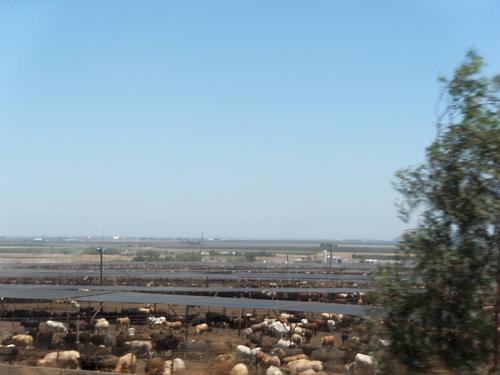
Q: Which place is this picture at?
A: It is at the pasture.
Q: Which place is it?
A: It is a pasture.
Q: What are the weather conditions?
A: It is clear.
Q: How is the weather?
A: It is clear.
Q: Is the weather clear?
A: Yes, it is clear.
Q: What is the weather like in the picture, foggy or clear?
A: It is clear.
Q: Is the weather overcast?
A: No, it is clear.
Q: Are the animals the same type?
A: Yes, all the animals are cows.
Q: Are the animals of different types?
A: No, all the animals are cows.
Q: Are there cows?
A: Yes, there is a cow.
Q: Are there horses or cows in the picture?
A: Yes, there is a cow.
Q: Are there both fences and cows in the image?
A: Yes, there are both a cow and a fence.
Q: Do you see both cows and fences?
A: Yes, there are both a cow and a fence.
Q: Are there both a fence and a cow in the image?
A: Yes, there are both a cow and a fence.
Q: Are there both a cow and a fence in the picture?
A: Yes, there are both a cow and a fence.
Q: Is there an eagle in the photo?
A: No, there are no eagles.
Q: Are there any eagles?
A: No, there are no eagles.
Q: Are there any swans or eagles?
A: No, there are no eagles or swans.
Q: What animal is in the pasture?
A: The animal is a cow.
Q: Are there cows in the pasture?
A: Yes, there is a cow in the pasture.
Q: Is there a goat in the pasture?
A: No, there is a cow in the pasture.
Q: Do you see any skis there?
A: No, there are no skis.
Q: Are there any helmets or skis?
A: No, there are no skis or helmets.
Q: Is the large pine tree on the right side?
A: Yes, the pine is on the right of the image.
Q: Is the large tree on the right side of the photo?
A: Yes, the pine is on the right of the image.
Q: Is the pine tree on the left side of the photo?
A: No, the pine tree is on the right of the image.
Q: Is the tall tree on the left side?
A: No, the pine tree is on the right of the image.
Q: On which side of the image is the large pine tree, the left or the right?
A: The pine is on the right of the image.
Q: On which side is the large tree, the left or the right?
A: The pine is on the right of the image.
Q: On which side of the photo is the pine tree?
A: The pine tree is on the right of the image.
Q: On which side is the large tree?
A: The pine tree is on the right of the image.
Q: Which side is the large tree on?
A: The pine tree is on the right of the image.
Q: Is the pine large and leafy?
A: Yes, the pine is large and leafy.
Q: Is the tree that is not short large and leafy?
A: Yes, the pine is large and leafy.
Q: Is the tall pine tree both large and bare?
A: No, the pine is large but leafy.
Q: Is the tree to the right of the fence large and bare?
A: No, the pine is large but leafy.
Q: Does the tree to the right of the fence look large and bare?
A: No, the pine is large but leafy.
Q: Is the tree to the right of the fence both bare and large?
A: No, the pine is large but leafy.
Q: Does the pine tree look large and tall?
A: Yes, the pine tree is large and tall.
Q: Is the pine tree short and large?
A: No, the pine tree is large but tall.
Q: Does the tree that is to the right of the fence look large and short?
A: No, the pine tree is large but tall.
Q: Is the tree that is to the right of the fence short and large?
A: No, the pine tree is large but tall.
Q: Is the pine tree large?
A: Yes, the pine tree is large.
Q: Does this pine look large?
A: Yes, the pine is large.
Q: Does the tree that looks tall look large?
A: Yes, the pine is large.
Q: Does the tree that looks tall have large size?
A: Yes, the pine is large.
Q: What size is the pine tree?
A: The pine tree is large.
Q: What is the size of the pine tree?
A: The pine tree is large.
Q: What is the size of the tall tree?
A: The pine tree is large.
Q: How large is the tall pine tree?
A: The pine is large.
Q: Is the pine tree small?
A: No, the pine tree is large.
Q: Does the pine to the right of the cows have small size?
A: No, the pine is large.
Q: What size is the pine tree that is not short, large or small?
A: The pine tree is large.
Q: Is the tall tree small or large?
A: The pine tree is large.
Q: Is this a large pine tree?
A: Yes, this is a large pine tree.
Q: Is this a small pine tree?
A: No, this is a large pine tree.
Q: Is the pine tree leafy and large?
A: Yes, the pine tree is leafy and large.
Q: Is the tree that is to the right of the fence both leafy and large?
A: Yes, the pine tree is leafy and large.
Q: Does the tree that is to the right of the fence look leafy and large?
A: Yes, the pine tree is leafy and large.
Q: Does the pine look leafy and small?
A: No, the pine is leafy but large.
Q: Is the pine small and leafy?
A: No, the pine is leafy but large.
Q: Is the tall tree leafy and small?
A: No, the pine is leafy but large.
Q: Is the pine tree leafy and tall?
A: Yes, the pine tree is leafy and tall.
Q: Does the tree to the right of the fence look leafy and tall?
A: Yes, the pine tree is leafy and tall.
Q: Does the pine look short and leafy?
A: No, the pine is leafy but tall.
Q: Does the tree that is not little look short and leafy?
A: No, the pine is leafy but tall.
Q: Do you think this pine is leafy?
A: Yes, the pine is leafy.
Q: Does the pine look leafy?
A: Yes, the pine is leafy.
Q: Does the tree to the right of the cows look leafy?
A: Yes, the pine is leafy.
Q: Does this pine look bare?
A: No, the pine is leafy.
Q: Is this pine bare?
A: No, the pine is leafy.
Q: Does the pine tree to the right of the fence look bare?
A: No, the pine tree is leafy.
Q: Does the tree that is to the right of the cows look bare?
A: No, the pine tree is leafy.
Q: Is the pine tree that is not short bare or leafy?
A: The pine is leafy.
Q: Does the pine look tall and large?
A: Yes, the pine is tall and large.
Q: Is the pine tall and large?
A: Yes, the pine is tall and large.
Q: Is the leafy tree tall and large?
A: Yes, the pine is tall and large.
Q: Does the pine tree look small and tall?
A: No, the pine tree is tall but large.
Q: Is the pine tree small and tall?
A: No, the pine tree is tall but large.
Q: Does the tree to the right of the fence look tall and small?
A: No, the pine tree is tall but large.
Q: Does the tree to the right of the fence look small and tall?
A: No, the pine tree is tall but large.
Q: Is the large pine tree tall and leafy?
A: Yes, the pine tree is tall and leafy.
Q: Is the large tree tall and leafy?
A: Yes, the pine tree is tall and leafy.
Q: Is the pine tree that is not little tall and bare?
A: No, the pine tree is tall but leafy.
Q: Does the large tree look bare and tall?
A: No, the pine tree is tall but leafy.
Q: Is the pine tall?
A: Yes, the pine is tall.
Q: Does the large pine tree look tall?
A: Yes, the pine tree is tall.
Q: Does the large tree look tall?
A: Yes, the pine tree is tall.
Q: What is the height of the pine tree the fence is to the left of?
A: The pine tree is tall.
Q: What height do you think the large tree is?
A: The pine tree is tall.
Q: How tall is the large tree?
A: The pine is tall.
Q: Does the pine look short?
A: No, the pine is tall.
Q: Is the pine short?
A: No, the pine is tall.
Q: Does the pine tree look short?
A: No, the pine tree is tall.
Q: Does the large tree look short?
A: No, the pine tree is tall.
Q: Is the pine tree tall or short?
A: The pine tree is tall.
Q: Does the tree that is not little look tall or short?
A: The pine tree is tall.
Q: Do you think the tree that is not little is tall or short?
A: The pine tree is tall.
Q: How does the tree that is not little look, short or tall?
A: The pine tree is tall.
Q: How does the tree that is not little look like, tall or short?
A: The pine tree is tall.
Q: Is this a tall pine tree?
A: Yes, this is a tall pine tree.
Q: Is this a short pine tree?
A: No, this is a tall pine tree.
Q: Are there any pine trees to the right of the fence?
A: Yes, there is a pine tree to the right of the fence.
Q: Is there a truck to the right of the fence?
A: No, there is a pine tree to the right of the fence.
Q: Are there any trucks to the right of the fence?
A: No, there is a pine tree to the right of the fence.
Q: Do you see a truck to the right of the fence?
A: No, there is a pine tree to the right of the fence.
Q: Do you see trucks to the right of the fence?
A: No, there is a pine tree to the right of the fence.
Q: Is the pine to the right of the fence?
A: Yes, the pine is to the right of the fence.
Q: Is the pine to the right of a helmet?
A: No, the pine is to the right of the fence.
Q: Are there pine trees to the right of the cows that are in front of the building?
A: Yes, there is a pine tree to the right of the cows.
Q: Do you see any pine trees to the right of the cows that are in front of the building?
A: Yes, there is a pine tree to the right of the cows.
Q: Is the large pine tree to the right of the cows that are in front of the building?
A: Yes, the pine is to the right of the cows.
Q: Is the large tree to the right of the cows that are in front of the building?
A: Yes, the pine is to the right of the cows.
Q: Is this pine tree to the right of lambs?
A: No, the pine tree is to the right of the cows.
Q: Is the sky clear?
A: Yes, the sky is clear.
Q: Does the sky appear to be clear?
A: Yes, the sky is clear.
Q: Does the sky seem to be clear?
A: Yes, the sky is clear.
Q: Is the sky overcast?
A: No, the sky is clear.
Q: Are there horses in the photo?
A: No, there are no horses.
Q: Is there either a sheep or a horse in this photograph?
A: No, there are no horses or sheep.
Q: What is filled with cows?
A: The pasture is filled with cows.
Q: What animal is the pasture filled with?
A: The pasture is filled with cows.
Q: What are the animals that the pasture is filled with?
A: The animals are cows.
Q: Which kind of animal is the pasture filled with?
A: The pasture is filled with cows.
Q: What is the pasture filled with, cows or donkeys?
A: The pasture is filled with cows.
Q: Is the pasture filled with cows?
A: Yes, the pasture is filled with cows.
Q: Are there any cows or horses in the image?
A: Yes, there is a cow.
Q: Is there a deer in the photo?
A: No, there is no deer.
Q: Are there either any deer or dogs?
A: No, there are no deer or dogs.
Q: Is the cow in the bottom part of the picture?
A: Yes, the cow is in the bottom of the image.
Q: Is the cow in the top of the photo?
A: No, the cow is in the bottom of the image.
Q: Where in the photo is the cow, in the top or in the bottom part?
A: The cow is in the bottom of the image.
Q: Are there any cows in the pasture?
A: Yes, there is a cow in the pasture.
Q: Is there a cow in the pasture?
A: Yes, there is a cow in the pasture.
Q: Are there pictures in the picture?
A: No, there are no pictures.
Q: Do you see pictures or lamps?
A: No, there are no pictures or lamps.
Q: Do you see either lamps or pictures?
A: No, there are no pictures or lamps.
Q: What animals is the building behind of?
A: The building is behind the cows.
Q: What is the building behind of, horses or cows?
A: The building is behind cows.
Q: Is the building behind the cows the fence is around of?
A: Yes, the building is behind the cows.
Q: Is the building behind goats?
A: No, the building is behind the cows.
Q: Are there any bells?
A: No, there are no bells.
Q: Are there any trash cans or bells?
A: No, there are no bells or trash cans.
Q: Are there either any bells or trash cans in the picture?
A: No, there are no bells or trash cans.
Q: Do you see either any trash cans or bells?
A: No, there are no bells or trash cans.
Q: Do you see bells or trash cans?
A: No, there are no bells or trash cans.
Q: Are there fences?
A: Yes, there is a fence.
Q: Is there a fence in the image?
A: Yes, there is a fence.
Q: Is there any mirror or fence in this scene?
A: Yes, there is a fence.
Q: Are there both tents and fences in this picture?
A: No, there is a fence but no tents.